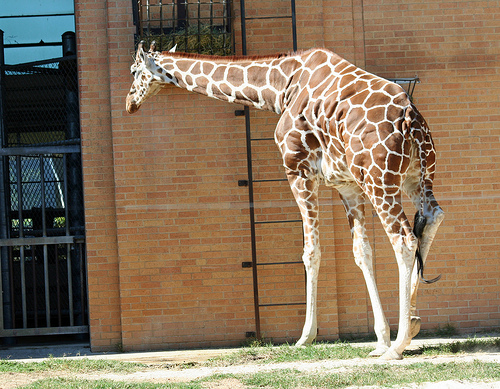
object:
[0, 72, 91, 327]
fence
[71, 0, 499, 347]
building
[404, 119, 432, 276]
tail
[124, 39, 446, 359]
giraffe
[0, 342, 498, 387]
turf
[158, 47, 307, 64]
mane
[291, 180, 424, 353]
legs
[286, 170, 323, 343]
leg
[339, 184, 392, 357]
leg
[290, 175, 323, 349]
leg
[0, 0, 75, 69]
sky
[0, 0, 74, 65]
clouds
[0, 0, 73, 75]
blue sky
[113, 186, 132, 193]
brick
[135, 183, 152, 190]
brick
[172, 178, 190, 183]
brick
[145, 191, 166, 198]
brick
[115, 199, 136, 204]
brick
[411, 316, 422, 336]
hoof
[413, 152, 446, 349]
legs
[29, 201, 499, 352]
bare patch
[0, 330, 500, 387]
ground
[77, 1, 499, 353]
wall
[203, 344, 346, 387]
green grass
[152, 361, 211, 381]
dirt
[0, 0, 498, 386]
pen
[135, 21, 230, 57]
troth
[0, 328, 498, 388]
grass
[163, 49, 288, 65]
hair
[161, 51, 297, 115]
neck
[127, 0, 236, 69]
metal cover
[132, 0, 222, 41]
bars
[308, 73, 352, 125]
spots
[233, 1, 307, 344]
ladder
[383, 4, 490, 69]
bricks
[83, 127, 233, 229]
bricks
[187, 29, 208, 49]
straw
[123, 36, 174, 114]
head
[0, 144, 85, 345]
barrier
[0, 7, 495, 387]
giraffe pen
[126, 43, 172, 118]
head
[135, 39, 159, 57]
horns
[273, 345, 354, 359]
grass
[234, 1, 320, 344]
escape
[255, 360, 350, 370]
patch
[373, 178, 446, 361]
legs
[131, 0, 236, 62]
windows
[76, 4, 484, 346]
building